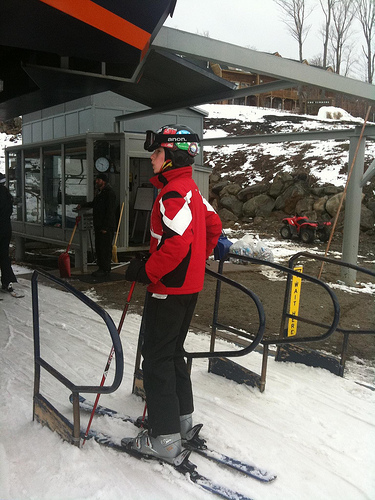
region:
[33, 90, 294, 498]
man wearing skis in snow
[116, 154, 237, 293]
man wearing red jacket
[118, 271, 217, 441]
man wearing black pants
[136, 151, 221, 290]
red jacket has white and black patches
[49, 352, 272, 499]
ski strap in is grey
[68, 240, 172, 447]
man holding ski pole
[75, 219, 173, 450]
ski pole is red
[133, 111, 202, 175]
man has goggle around head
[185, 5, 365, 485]
read atv in background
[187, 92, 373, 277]
rocky hill next to atv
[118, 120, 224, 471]
Boy waiting at the ski lift entrance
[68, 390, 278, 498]
Two skis in the snow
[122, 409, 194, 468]
Ski boots on boy's feet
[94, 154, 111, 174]
Clock in the ski lift shack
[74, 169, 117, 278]
Man standing in front of ski lift shack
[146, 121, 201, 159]
Helmet and goggles on boy's head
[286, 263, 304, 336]
Yellow sign saying Wait Here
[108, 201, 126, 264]
Broom resting against the ski lift shack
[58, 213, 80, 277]
Red shovel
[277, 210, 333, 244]
Red 4x4 vehicle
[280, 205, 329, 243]
Small red and black truck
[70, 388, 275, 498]
Skiis and ski boots on the snow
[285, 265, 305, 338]
Small yellow sign that says wait here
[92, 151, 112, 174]
Small round clock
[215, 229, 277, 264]
Trashcan spilled over with trash bags on the ground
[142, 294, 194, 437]
Black snow pants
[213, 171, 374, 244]
A bunch of boulder rocks next to a vehicle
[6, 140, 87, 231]
Four windows on a building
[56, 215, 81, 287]
Red shovel on the ground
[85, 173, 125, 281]
Man wearing black standing next to a broom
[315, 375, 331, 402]
white snow on ground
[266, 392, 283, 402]
white snow on ground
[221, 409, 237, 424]
white snow on ground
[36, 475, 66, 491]
white snow on ground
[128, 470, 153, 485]
white snow on ground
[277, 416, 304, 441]
white snow on ground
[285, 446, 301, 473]
white snow on ground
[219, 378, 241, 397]
white snow on ground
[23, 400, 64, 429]
white snow on ground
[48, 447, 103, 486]
white snow on ground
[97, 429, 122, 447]
skiis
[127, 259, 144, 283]
person is wearing black gloves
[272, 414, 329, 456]
the snow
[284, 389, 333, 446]
the snow is white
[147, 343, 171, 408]
black pants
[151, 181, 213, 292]
a jacket the person is wearing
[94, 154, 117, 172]
a small clock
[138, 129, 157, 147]
ski goggles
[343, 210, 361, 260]
a metal pole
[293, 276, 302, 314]
a yellow sign